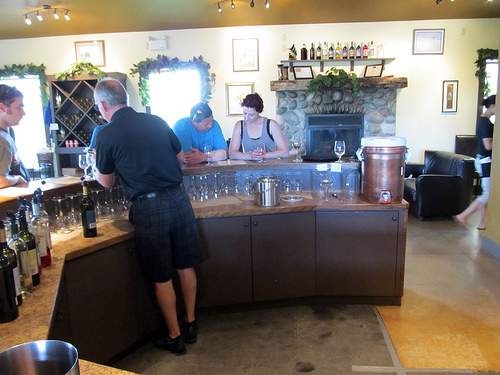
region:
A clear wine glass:
[332, 137, 349, 164]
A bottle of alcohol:
[73, 179, 100, 243]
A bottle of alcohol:
[31, 199, 61, 267]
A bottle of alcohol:
[15, 211, 47, 288]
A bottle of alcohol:
[2, 234, 27, 303]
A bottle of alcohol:
[2, 260, 20, 332]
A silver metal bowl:
[1, 339, 84, 373]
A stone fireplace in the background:
[267, 78, 408, 154]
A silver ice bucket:
[247, 176, 284, 209]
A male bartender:
[85, 77, 220, 358]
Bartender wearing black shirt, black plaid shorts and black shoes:
[88, 74, 208, 359]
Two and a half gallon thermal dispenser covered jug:
[360, 141, 406, 206]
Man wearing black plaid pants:
[93, 75, 211, 292]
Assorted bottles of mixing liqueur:
[0, 186, 59, 325]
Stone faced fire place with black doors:
[272, 77, 409, 159]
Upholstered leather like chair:
[402, 150, 477, 225]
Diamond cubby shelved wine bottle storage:
[41, 70, 132, 150]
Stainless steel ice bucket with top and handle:
[254, 175, 282, 207]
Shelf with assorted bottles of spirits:
[283, 39, 395, 65]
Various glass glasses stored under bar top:
[188, 162, 345, 199]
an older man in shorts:
[86, 76, 208, 356]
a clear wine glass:
[332, 139, 345, 164]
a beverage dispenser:
[357, 135, 407, 202]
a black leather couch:
[400, 148, 475, 222]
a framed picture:
[410, 26, 445, 56]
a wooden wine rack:
[46, 72, 128, 180]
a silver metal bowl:
[0, 338, 82, 374]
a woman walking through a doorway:
[451, 94, 497, 231]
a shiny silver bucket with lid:
[245, 174, 281, 209]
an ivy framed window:
[127, 53, 217, 129]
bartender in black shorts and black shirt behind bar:
[0, 74, 410, 373]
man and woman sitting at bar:
[171, 91, 296, 162]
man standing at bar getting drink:
[0, 83, 30, 189]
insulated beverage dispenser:
[358, 136, 405, 202]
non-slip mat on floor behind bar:
[140, 305, 401, 370]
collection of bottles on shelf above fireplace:
[285, 40, 375, 56]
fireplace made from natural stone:
[270, 76, 408, 156]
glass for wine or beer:
[333, 139, 345, 161]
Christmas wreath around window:
[131, 55, 216, 115]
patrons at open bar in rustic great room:
[0, 14, 495, 372]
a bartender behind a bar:
[87, 78, 203, 354]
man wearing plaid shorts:
[126, 183, 203, 282]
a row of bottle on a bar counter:
[1, 188, 51, 321]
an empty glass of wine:
[332, 140, 347, 162]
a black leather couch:
[404, 150, 474, 217]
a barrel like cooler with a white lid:
[359, 136, 406, 206]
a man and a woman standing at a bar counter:
[171, 91, 291, 164]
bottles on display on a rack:
[52, 78, 112, 142]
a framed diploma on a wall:
[413, 28, 445, 54]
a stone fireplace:
[273, 78, 408, 158]